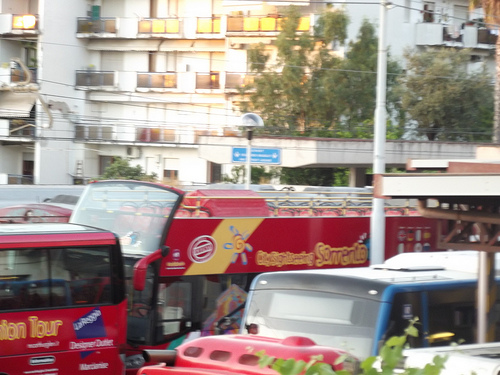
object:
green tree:
[231, 9, 409, 190]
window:
[0, 246, 123, 311]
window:
[153, 277, 195, 343]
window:
[65, 182, 182, 257]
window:
[120, 260, 156, 347]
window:
[199, 275, 252, 332]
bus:
[0, 220, 132, 374]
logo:
[187, 233, 219, 265]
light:
[236, 112, 266, 127]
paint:
[166, 217, 368, 275]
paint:
[0, 303, 126, 363]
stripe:
[216, 217, 271, 273]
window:
[397, 290, 424, 350]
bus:
[239, 249, 500, 375]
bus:
[59, 175, 495, 375]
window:
[428, 286, 478, 346]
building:
[0, 0, 500, 187]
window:
[243, 271, 388, 358]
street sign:
[231, 146, 283, 166]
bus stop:
[370, 145, 500, 375]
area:
[367, 153, 500, 375]